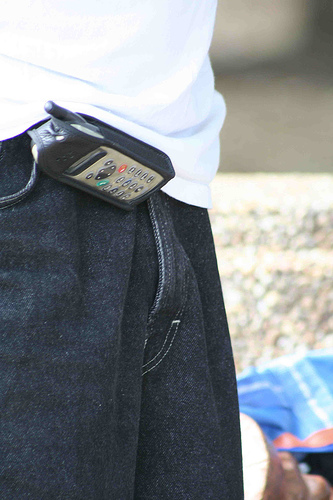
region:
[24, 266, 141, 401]
The pants are dark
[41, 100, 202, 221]
The phone has buttons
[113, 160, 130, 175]
The button is red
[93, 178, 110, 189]
The button is green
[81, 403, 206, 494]
The pants are denim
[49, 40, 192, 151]
The shirt is white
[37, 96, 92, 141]
The phone has an antenna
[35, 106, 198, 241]
The phone is in a case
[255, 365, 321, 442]
Something is blue in the back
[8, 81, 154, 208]
The phone is on the belt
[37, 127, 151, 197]
cell phone in jeans pocket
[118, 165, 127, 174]
button on the phone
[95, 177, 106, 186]
button on the phone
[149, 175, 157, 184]
button on the phone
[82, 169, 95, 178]
button on the phone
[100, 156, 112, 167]
button on the phone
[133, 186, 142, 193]
button on the phone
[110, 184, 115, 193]
button on the phone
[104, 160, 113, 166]
button on the phone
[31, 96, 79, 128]
antenna on the phone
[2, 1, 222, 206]
an untucked white t-shirt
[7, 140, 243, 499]
a pair of dark wash blue jeans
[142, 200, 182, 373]
the fly on the jeans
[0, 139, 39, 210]
a front pocket on the jeans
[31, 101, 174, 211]
a cellphone in a leather case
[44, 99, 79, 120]
the cellphone antenna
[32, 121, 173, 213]
black leather case on phone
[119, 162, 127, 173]
red button on the phone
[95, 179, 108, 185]
green button on the phone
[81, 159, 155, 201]
keypad on the cellphone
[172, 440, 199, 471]
the pants are blue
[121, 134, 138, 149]
the case is black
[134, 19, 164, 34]
the shirt is white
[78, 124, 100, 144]
the phone is in the case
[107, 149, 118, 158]
the phone is gray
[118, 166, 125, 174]
the button is red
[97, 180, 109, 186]
the button is green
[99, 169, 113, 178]
the button is black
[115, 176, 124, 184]
the letters are white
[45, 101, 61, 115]
the antenna is black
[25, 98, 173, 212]
a black phone case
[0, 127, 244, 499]
a pair of dark denim pants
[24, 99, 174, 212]
a phone with a black antenna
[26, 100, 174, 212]
the phone has red, green, and black buttons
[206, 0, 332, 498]
a blurry background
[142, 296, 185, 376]
double white seams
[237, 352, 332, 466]
a blue and white towel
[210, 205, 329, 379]
gray colored sand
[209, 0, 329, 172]
gray colored pavement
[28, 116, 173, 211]
the phone case with a clear front